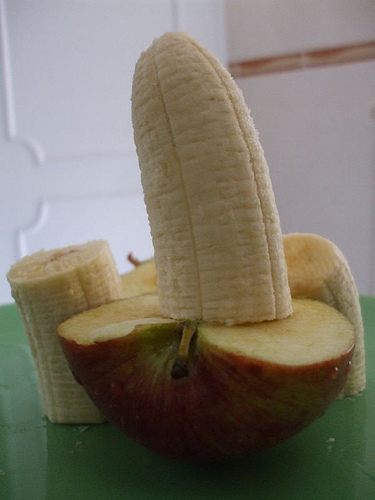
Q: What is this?
A: Fruit.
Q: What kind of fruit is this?
A: Apple and banana.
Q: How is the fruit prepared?
A: Sliced.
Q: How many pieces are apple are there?
A: One.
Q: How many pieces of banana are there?
A: Three.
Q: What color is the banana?
A: White.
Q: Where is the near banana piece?
A: On top of the apple.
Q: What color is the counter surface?
A: Green.